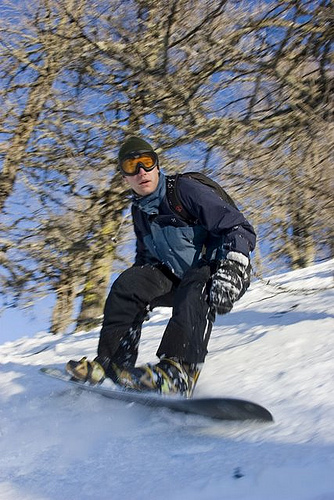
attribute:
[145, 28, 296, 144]
tree — tall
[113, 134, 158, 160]
hat — black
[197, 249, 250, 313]
gloves — black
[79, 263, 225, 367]
pants — black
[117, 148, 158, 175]
googles — yellow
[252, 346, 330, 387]
snow — covered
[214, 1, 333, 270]
tree — tall, growing 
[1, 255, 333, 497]
hill — covered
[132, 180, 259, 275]
jacket — blue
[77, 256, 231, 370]
pants — black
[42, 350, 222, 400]
feet —  man's feet.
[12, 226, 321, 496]
hill — tall